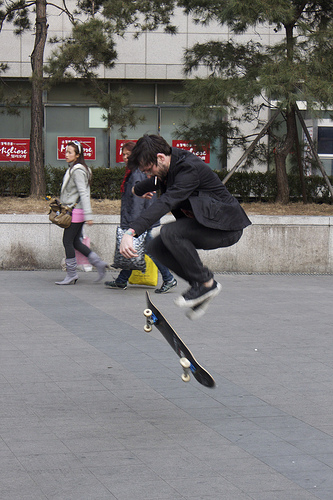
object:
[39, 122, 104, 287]
smiling woman